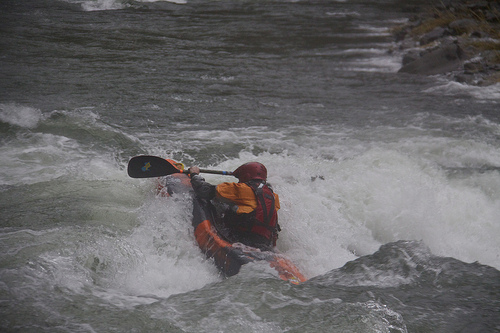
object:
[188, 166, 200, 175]
hand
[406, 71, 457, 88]
rock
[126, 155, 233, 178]
oar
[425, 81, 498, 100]
rock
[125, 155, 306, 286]
canoe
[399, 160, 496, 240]
waters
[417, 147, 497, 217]
waves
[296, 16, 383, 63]
river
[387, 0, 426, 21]
rocks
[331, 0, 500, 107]
shoreline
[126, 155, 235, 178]
row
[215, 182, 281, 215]
life vest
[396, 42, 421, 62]
rock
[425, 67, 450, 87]
rock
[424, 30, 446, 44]
rock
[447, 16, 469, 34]
rock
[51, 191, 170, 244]
water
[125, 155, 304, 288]
kayak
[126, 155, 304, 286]
boat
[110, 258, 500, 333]
waves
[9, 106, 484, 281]
wave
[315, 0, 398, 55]
water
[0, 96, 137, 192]
waves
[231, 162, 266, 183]
helmet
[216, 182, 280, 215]
jacket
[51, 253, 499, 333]
rock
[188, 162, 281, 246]
man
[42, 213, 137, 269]
river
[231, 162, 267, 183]
hat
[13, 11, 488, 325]
canoing scene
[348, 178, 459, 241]
waters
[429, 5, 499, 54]
mounds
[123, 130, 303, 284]
kayaker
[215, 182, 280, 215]
vest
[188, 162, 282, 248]
boarder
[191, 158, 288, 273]
kayaker